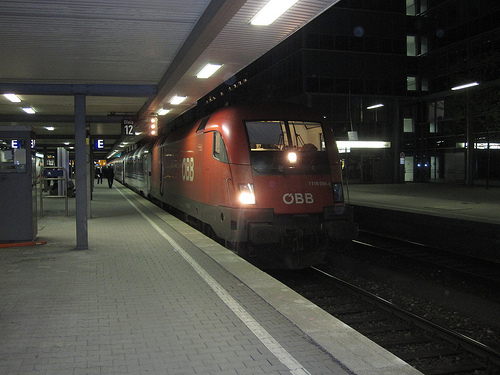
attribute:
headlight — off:
[332, 177, 347, 212]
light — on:
[222, 177, 284, 215]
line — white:
[111, 180, 313, 374]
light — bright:
[235, 193, 252, 208]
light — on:
[3, 94, 22, 105]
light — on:
[23, 105, 37, 116]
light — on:
[252, 0, 299, 27]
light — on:
[195, 56, 221, 83]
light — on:
[169, 90, 189, 106]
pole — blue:
[68, 94, 93, 254]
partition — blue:
[0, 129, 38, 246]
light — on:
[174, 37, 256, 104]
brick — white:
[22, 288, 183, 335]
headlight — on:
[233, 180, 267, 207]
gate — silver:
[37, 152, 73, 219]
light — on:
[194, 60, 224, 82]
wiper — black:
[293, 131, 308, 146]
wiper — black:
[273, 127, 288, 148]